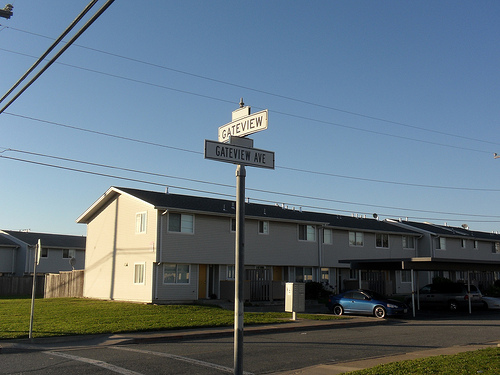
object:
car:
[320, 285, 418, 325]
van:
[404, 278, 486, 315]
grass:
[1, 292, 352, 336]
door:
[195, 261, 211, 301]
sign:
[201, 137, 282, 173]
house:
[74, 185, 425, 309]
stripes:
[35, 339, 260, 375]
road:
[1, 303, 500, 373]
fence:
[0, 269, 82, 300]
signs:
[202, 108, 272, 146]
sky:
[0, 1, 500, 235]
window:
[129, 259, 150, 287]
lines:
[36, 340, 152, 375]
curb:
[356, 317, 388, 325]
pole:
[230, 168, 252, 375]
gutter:
[153, 206, 333, 229]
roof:
[110, 180, 428, 240]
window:
[340, 292, 369, 301]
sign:
[32, 236, 45, 267]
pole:
[22, 244, 43, 345]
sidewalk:
[275, 340, 500, 374]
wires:
[0, 0, 500, 223]